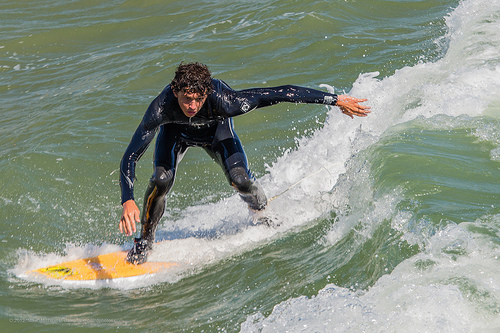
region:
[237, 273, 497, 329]
The ocean water is white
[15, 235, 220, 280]
The surfboard is yellow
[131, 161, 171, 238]
The leg of the surfer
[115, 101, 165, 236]
The arm of the surfer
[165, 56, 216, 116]
The head of the surfer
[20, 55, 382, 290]
A man surfing in the ocean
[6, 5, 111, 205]
The water in the ocean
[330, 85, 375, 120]
The hand in the ocean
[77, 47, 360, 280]
The surfer is wearing a wet suit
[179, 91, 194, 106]
The eye of the surfer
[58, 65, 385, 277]
the man in the ocean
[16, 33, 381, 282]
the man on the surfboard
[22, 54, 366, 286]
the man is surfing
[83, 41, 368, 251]
the man wearing a wet suit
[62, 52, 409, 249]
the man is wet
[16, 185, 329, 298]
the surfboard is yellow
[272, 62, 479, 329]
the wave in the ocean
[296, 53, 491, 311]
the wave is cresting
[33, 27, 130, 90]
the water is green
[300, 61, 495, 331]
the water is foaming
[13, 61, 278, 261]
young man in black wet suit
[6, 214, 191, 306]
yellow and white surf board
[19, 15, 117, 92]
green and white ocean waves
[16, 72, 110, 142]
green and white ocean waves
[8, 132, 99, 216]
green and white ocean waves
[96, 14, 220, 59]
green and white ocean waves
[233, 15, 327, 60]
green and white ocean waves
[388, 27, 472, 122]
green and white ocean waves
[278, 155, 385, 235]
green and white ocean waves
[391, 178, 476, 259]
green and white ocean waves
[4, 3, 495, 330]
A vast expanse of water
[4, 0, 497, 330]
The open sea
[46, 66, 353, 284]
A man surfing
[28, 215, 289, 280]
A slim yellow surfboard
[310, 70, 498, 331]
A small ocean wave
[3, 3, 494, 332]
A ocean with a small wave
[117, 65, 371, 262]
A man in a wetsuit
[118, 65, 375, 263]
A man in a black wetsuit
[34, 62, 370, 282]
A man in a black wetsuit on a yellow surfboard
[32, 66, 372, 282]
A man with short dark hair surfing in the ocean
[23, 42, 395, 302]
The man is on a surfboard.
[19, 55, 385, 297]
The surfboard is yellow.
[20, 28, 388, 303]
The surfboard is in water.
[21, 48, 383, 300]
The surfboard is wet.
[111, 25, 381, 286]
Man left arm is outstretched.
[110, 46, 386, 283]
The man is wearing a wetsuit.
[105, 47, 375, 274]
The wetsuit is wet.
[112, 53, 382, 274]
The man has curly hair.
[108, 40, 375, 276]
The man's hair is wet.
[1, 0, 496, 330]
The water is wavy.